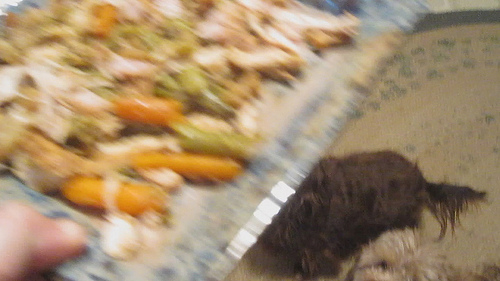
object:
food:
[0, 0, 271, 256]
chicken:
[0, 0, 352, 214]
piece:
[213, 39, 304, 79]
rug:
[230, 0, 498, 281]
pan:
[0, 0, 427, 281]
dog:
[264, 149, 484, 281]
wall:
[231, 143, 280, 189]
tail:
[424, 178, 489, 243]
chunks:
[14, 41, 105, 158]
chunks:
[163, 14, 293, 85]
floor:
[229, 0, 500, 281]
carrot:
[88, 2, 118, 38]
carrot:
[111, 90, 191, 123]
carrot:
[130, 149, 240, 179]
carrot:
[68, 175, 158, 211]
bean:
[174, 125, 253, 153]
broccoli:
[152, 56, 235, 115]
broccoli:
[112, 19, 172, 53]